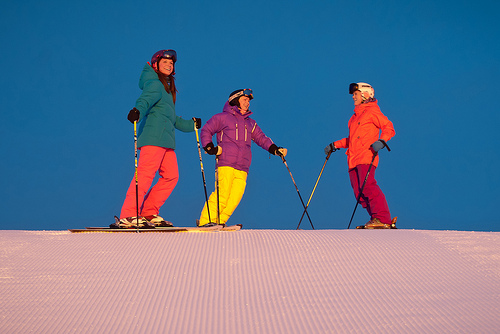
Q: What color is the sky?
A: Blue.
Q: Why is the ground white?
A: Snow.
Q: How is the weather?
A: Cold and clear.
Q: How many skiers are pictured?
A: Three.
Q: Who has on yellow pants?
A: Person in the middle.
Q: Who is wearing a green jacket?
A: Person on left.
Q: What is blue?
A: Sky.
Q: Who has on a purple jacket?
A: Person in the middle.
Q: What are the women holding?
A: Ski poles.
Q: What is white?
A: Snow.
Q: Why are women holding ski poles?
A: To ski.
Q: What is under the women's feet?
A: Skis.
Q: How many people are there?
A: Three.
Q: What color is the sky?
A: Blue.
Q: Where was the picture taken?
A: Canada.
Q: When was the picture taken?
A: Morning.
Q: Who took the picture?
A: A photographer.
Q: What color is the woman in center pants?
A: Yellow.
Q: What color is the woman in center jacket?
A: Purple.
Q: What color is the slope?
A: White.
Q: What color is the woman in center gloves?
A: Black.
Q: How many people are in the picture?
A: 3.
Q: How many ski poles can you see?
A: 6.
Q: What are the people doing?
A: Skiing.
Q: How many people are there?
A: Three.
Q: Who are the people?
A: Women.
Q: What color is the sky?
A: Blue.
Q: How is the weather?
A: Clear.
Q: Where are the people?
A: Ski slope.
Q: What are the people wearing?
A: Snowpants.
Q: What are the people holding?
A: Poles.